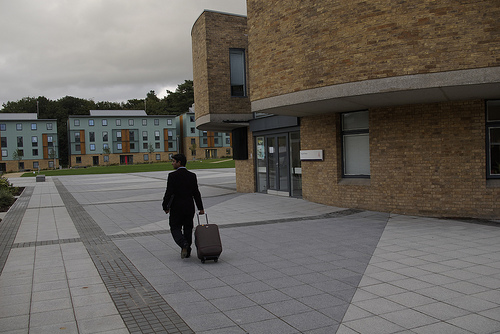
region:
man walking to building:
[6, 12, 261, 327]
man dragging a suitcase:
[153, 138, 236, 273]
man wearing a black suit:
[148, 145, 240, 277]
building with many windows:
[0, 94, 250, 175]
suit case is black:
[188, 205, 233, 272]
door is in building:
[190, 11, 491, 231]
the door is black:
[243, 115, 313, 207]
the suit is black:
[158, 149, 213, 268]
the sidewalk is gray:
[25, 172, 497, 329]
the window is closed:
[333, 101, 380, 187]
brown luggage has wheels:
[195, 211, 224, 262]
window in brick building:
[227, 47, 247, 101]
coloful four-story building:
[0, 112, 60, 173]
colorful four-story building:
[67, 107, 230, 167]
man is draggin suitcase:
[164, 153, 226, 263]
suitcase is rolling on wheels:
[194, 213, 221, 256]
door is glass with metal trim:
[263, 133, 279, 192]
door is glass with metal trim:
[279, 136, 292, 191]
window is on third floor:
[88, 131, 97, 142]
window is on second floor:
[117, 143, 123, 152]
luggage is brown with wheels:
[194, 208, 222, 261]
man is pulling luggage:
[163, 153, 204, 260]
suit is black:
[162, 167, 203, 258]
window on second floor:
[229, 48, 244, 96]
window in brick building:
[337, 116, 369, 180]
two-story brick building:
[193, 0, 498, 220]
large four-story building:
[70, 107, 235, 167]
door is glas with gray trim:
[266, 137, 280, 190]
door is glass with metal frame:
[277, 136, 287, 193]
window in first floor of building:
[487, 95, 498, 185]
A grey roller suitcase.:
[192, 210, 222, 262]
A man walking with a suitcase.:
[162, 152, 204, 257]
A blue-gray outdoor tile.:
[207, 292, 257, 312]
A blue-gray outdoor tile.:
[224, 303, 279, 325]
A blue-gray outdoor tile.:
[302, 259, 343, 273]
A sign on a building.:
[297, 149, 324, 160]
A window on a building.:
[337, 109, 369, 178]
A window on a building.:
[228, 46, 245, 97]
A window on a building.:
[485, 100, 499, 190]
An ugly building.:
[67, 109, 176, 168]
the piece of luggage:
[189, 212, 223, 263]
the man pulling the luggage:
[160, 154, 204, 270]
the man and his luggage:
[154, 143, 227, 265]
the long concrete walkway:
[29, 181, 421, 331]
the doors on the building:
[248, 127, 308, 194]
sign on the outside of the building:
[298, 148, 326, 163]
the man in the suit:
[160, 156, 204, 257]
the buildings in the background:
[8, 110, 215, 177]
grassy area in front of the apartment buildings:
[26, 158, 229, 173]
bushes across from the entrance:
[2, 172, 22, 214]